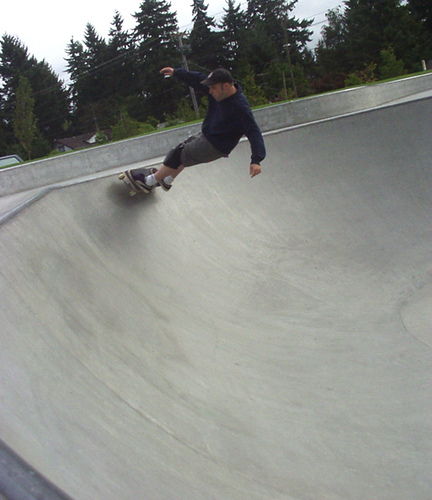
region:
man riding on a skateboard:
[117, 65, 265, 198]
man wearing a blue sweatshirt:
[133, 63, 267, 194]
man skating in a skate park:
[0, 60, 430, 499]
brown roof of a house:
[45, 125, 113, 151]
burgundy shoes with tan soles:
[126, 167, 173, 193]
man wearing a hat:
[125, 57, 265, 196]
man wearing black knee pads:
[117, 66, 266, 199]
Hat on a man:
[200, 64, 237, 93]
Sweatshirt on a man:
[172, 59, 272, 150]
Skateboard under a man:
[117, 163, 186, 216]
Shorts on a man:
[147, 126, 234, 177]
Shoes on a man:
[131, 164, 181, 195]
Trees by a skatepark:
[15, 13, 263, 116]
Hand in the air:
[151, 61, 181, 78]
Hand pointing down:
[245, 149, 274, 189]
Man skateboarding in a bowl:
[112, 61, 279, 202]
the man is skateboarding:
[102, 45, 290, 227]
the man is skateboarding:
[103, 56, 259, 201]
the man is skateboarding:
[116, 53, 261, 211]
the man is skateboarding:
[97, 42, 274, 233]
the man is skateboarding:
[125, 61, 281, 232]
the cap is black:
[197, 62, 235, 90]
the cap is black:
[182, 53, 244, 112]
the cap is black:
[197, 61, 246, 120]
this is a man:
[122, 28, 257, 174]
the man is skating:
[99, 57, 309, 224]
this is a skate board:
[103, 166, 167, 205]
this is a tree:
[129, 1, 201, 114]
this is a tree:
[7, 78, 46, 161]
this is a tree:
[1, 36, 78, 143]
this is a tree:
[49, 25, 119, 128]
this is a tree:
[320, 2, 397, 91]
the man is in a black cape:
[186, 67, 243, 102]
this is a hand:
[234, 97, 283, 190]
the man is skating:
[111, 51, 301, 213]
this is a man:
[155, 55, 288, 220]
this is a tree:
[3, 42, 57, 171]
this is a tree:
[4, 32, 71, 141]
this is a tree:
[56, 29, 136, 130]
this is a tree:
[81, 18, 174, 142]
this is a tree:
[102, 10, 177, 133]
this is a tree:
[140, 0, 204, 109]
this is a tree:
[188, 8, 253, 105]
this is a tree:
[224, 4, 306, 97]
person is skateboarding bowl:
[118, 62, 266, 199]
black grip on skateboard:
[117, 166, 165, 196]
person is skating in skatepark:
[0, 68, 431, 499]